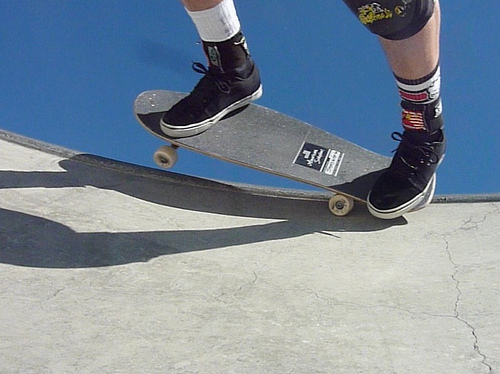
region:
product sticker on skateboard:
[294, 141, 343, 175]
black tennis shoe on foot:
[366, 126, 446, 218]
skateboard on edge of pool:
[132, 88, 436, 233]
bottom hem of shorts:
[343, 0, 442, 37]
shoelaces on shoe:
[389, 129, 439, 164]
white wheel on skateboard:
[326, 193, 353, 218]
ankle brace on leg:
[399, 95, 449, 135]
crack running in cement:
[420, 214, 495, 372]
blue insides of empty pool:
[4, 0, 496, 195]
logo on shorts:
[357, 2, 411, 21]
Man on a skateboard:
[133, 0, 448, 217]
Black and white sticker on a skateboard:
[292, 139, 344, 176]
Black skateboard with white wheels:
[134, 88, 437, 219]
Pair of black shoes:
[159, 62, 447, 219]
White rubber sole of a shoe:
[158, 85, 262, 142]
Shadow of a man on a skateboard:
[0, 152, 408, 272]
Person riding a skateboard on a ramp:
[133, 0, 448, 217]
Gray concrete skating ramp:
[0, 126, 495, 371]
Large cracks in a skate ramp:
[435, 198, 499, 370]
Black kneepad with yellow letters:
[344, 0, 436, 41]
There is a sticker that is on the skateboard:
[296, 122, 349, 188]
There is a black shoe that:
[393, 148, 436, 205]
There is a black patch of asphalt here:
[348, 261, 382, 315]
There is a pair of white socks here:
[195, 11, 221, 28]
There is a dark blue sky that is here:
[468, 81, 482, 138]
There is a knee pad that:
[357, 4, 407, 35]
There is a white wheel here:
[328, 195, 363, 223]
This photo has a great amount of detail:
[109, 57, 371, 371]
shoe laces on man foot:
[390, 126, 438, 162]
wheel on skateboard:
[146, 139, 184, 164]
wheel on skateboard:
[318, 193, 356, 214]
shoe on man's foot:
[368, 128, 448, 228]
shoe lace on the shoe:
[192, 59, 226, 91]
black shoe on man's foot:
[157, 66, 269, 138]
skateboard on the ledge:
[130, 69, 443, 211]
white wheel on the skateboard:
[150, 143, 178, 165]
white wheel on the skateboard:
[321, 192, 353, 215]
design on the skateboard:
[295, 137, 345, 174]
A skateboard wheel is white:
[145, 140, 184, 177]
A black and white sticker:
[291, 135, 348, 179]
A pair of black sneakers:
[155, 60, 451, 222]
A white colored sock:
[180, 0, 244, 46]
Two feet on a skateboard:
[131, 81, 443, 230]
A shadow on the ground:
[1, 152, 410, 271]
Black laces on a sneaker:
[387, 125, 444, 173]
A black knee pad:
[342, 1, 438, 45]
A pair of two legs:
[177, 0, 446, 116]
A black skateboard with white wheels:
[130, 83, 440, 224]